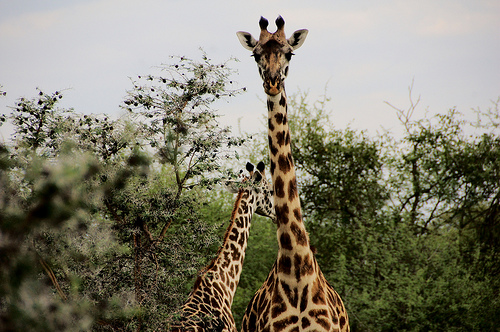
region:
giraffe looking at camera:
[237, 17, 314, 101]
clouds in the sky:
[7, 5, 121, 70]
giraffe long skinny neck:
[260, 103, 317, 280]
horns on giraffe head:
[257, 14, 287, 39]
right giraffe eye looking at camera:
[252, 51, 263, 63]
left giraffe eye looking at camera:
[285, 48, 297, 63]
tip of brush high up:
[110, 50, 235, 124]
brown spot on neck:
[275, 203, 292, 228]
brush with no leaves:
[382, 72, 431, 122]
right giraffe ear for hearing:
[235, 20, 260, 51]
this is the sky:
[342, 36, 445, 76]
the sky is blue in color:
[357, 51, 414, 78]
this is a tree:
[321, 145, 388, 255]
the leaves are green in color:
[328, 168, 373, 247]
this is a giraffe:
[240, 28, 312, 273]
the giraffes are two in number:
[176, 42, 299, 324]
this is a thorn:
[152, 239, 186, 267]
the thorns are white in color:
[172, 237, 188, 264]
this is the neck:
[269, 98, 299, 241]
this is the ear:
[288, 21, 307, 39]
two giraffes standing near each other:
[175, 16, 351, 326]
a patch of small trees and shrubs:
[16, 105, 466, 300]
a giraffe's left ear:
[286, 30, 308, 50]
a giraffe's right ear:
[230, 25, 250, 56]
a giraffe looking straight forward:
[236, 20, 371, 325]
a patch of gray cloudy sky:
[2, 2, 495, 179]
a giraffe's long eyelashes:
[250, 48, 300, 60]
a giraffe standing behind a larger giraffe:
[147, 145, 248, 328]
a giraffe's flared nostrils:
[262, 77, 284, 92]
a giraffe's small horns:
[250, 6, 295, 36]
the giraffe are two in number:
[157, 17, 334, 330]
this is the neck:
[263, 110, 315, 221]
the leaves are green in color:
[333, 164, 360, 214]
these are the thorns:
[197, 238, 214, 242]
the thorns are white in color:
[146, 261, 155, 287]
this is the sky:
[331, 12, 461, 69]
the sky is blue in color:
[83, 19, 125, 73]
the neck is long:
[263, 120, 308, 251]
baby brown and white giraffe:
[155, 154, 280, 330]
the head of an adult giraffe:
[234, 14, 309, 97]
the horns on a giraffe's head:
[256, 14, 288, 44]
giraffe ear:
[233, 27, 259, 51]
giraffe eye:
[283, 47, 293, 59]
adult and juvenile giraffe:
[159, 7, 356, 329]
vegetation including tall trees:
[3, 54, 488, 329]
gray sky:
[3, 3, 498, 162]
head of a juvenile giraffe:
[221, 158, 274, 217]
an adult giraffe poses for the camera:
[236, 14, 351, 330]